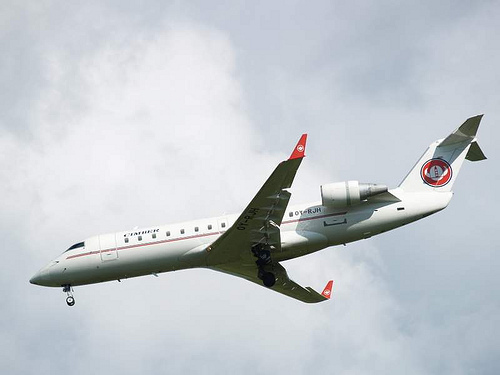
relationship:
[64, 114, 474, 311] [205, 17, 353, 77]
plane in sky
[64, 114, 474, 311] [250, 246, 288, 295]
plane has wheels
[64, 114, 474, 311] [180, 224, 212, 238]
plane has windows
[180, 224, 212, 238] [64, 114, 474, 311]
windows on plane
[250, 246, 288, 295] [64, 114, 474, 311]
wheels on plane